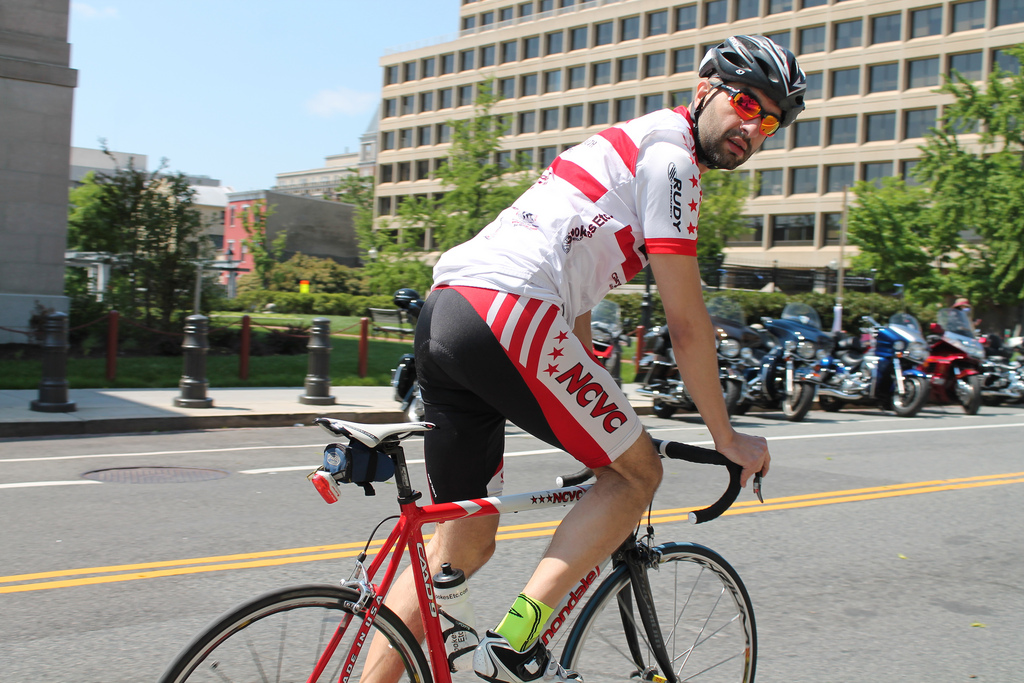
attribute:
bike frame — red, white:
[237, 435, 659, 675]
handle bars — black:
[620, 404, 862, 592]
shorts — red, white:
[360, 245, 642, 498]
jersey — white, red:
[403, 102, 793, 368]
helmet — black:
[688, 1, 866, 207]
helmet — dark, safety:
[693, 46, 843, 118]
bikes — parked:
[648, 296, 960, 407]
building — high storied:
[380, 7, 1007, 301]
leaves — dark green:
[818, 100, 1007, 317]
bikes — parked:
[678, 286, 974, 403]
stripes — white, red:
[449, 268, 620, 426]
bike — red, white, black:
[284, 385, 894, 660]